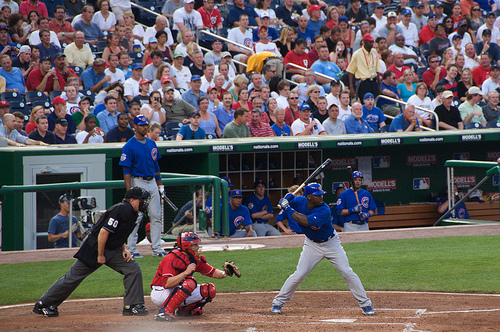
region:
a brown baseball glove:
[222, 256, 244, 279]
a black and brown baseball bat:
[284, 155, 335, 195]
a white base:
[316, 314, 358, 324]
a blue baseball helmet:
[304, 180, 326, 196]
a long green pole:
[5, 173, 220, 195]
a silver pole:
[376, 93, 441, 129]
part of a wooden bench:
[365, 200, 498, 230]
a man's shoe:
[357, 301, 376, 314]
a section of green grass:
[0, 232, 499, 310]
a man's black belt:
[306, 233, 337, 243]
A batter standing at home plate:
[269, 156, 379, 315]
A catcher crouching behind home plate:
[142, 230, 243, 321]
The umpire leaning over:
[31, 185, 155, 315]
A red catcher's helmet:
[172, 228, 208, 260]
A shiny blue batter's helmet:
[302, 177, 326, 199]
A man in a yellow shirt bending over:
[240, 47, 287, 77]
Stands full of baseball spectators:
[1, 1, 498, 151]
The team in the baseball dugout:
[166, 161, 473, 233]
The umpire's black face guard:
[123, 183, 153, 213]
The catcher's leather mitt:
[220, 258, 242, 278]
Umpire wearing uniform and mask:
[31, 187, 152, 318]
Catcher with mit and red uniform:
[146, 225, 242, 317]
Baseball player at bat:
[270, 155, 377, 319]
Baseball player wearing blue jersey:
[270, 153, 379, 318]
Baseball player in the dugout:
[330, 132, 387, 237]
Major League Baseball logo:
[409, 173, 433, 193]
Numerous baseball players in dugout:
[220, 137, 394, 238]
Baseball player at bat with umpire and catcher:
[30, 156, 386, 315]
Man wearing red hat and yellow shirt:
[347, 32, 387, 98]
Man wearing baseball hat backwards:
[357, 90, 391, 132]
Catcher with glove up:
[148, 229, 241, 322]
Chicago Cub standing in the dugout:
[337, 172, 378, 230]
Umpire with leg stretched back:
[30, 184, 152, 316]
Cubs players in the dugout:
[224, 168, 382, 238]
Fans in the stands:
[0, 1, 498, 142]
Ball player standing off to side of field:
[118, 114, 168, 256]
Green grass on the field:
[0, 226, 498, 302]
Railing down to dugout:
[437, 159, 499, 224]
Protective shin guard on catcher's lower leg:
[161, 275, 196, 316]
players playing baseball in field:
[28, 113, 387, 323]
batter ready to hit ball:
[244, 140, 391, 318]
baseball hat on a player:
[130, 110, 151, 126]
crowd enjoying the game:
[1, 25, 497, 137]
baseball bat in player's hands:
[345, 160, 363, 218]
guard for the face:
[136, 181, 153, 221]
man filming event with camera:
[44, 188, 97, 245]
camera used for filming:
[70, 192, 100, 214]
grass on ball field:
[370, 240, 498, 287]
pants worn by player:
[269, 235, 378, 305]